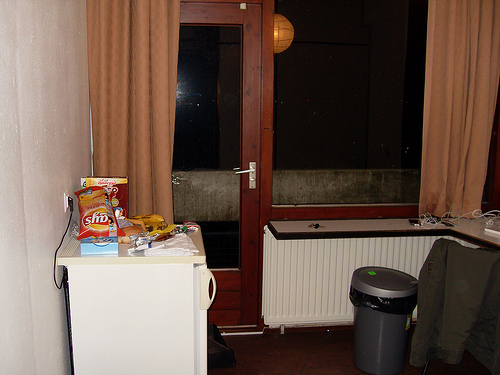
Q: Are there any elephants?
A: No, there are no elephants.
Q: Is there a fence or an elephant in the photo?
A: No, there are no elephants or fences.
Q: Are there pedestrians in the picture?
A: No, there are no pedestrians.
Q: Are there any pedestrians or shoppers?
A: No, there are no pedestrians or shoppers.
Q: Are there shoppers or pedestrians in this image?
A: No, there are no pedestrians or shoppers.